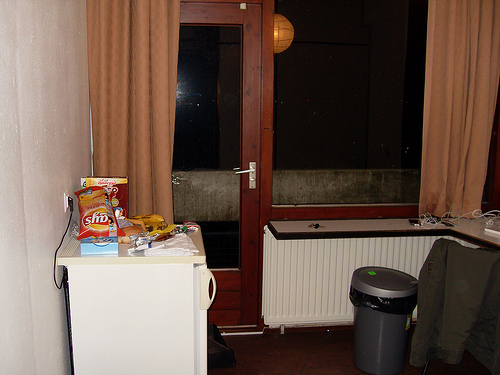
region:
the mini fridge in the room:
[64, 210, 225, 368]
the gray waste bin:
[330, 250, 410, 356]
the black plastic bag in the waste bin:
[351, 289, 421, 313]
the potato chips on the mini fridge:
[75, 169, 120, 268]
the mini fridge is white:
[71, 213, 222, 373]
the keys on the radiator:
[303, 213, 323, 228]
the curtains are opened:
[81, 5, 486, 227]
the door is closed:
[178, 15, 275, 315]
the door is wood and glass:
[186, 4, 263, 324]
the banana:
[127, 211, 170, 236]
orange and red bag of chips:
[70, 182, 127, 242]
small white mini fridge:
[56, 213, 209, 372]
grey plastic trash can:
[346, 263, 413, 370]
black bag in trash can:
[345, 280, 419, 319]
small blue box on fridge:
[75, 236, 122, 256]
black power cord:
[49, 187, 89, 294]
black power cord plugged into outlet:
[57, 188, 77, 214]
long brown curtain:
[87, 4, 179, 224]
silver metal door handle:
[226, 156, 263, 190]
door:
[169, 3, 271, 324]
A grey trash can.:
[347, 266, 417, 373]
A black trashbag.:
[349, 279, 419, 314]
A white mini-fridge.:
[57, 226, 216, 372]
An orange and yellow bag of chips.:
[75, 189, 125, 239]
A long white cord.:
[419, 207, 498, 226]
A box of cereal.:
[81, 174, 129, 216]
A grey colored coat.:
[404, 238, 496, 373]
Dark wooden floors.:
[215, 328, 496, 372]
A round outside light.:
[272, 14, 295, 53]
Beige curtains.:
[85, 0, 497, 226]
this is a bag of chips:
[72, 182, 122, 244]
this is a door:
[93, 0, 266, 337]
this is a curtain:
[81, 0, 195, 231]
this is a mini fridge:
[55, 210, 225, 374]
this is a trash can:
[332, 255, 422, 374]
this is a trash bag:
[344, 283, 424, 318]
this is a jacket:
[409, 227, 493, 374]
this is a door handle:
[229, 159, 266, 205]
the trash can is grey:
[331, 264, 430, 374]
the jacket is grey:
[400, 228, 497, 373]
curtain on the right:
[421, 1, 497, 216]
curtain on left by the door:
[86, 0, 177, 221]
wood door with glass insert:
[178, 1, 260, 328]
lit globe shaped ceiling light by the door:
[273, 12, 295, 55]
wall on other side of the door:
[172, 169, 418, 223]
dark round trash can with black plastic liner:
[351, 265, 418, 374]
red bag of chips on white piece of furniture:
[74, 185, 125, 240]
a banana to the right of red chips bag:
[132, 214, 168, 224]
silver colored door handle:
[234, 162, 256, 191]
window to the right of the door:
[274, 0, 426, 204]